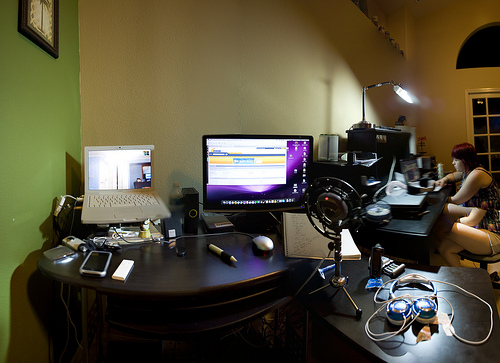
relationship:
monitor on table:
[203, 134, 313, 214] [25, 210, 317, 357]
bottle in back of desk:
[162, 171, 193, 226] [55, 208, 269, 314]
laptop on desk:
[80, 140, 177, 231] [32, 210, 390, 302]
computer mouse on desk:
[253, 234, 275, 253] [53, 191, 320, 346]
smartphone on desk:
[76, 246, 116, 281] [119, 234, 280, 305]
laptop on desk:
[401, 153, 442, 200] [34, 168, 464, 347]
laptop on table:
[78, 144, 170, 224] [33, 200, 360, 340]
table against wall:
[40, 234, 295, 305] [119, 19, 334, 124]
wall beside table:
[2, 0, 79, 362] [37, 210, 326, 292]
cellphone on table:
[80, 247, 117, 277] [130, 242, 282, 291]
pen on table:
[206, 239, 236, 265] [25, 210, 317, 357]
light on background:
[390, 83, 413, 104] [310, 36, 457, 123]